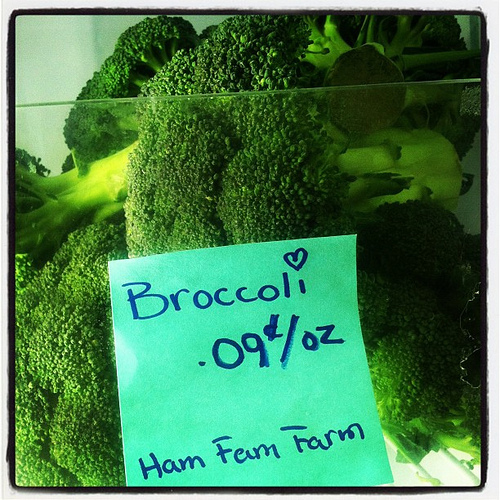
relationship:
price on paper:
[197, 310, 289, 381] [106, 228, 386, 496]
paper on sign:
[106, 228, 386, 496] [257, 309, 285, 344]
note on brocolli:
[106, 231, 396, 488] [17, 17, 479, 487]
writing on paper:
[260, 310, 279, 345] [106, 228, 386, 496]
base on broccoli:
[322, 51, 414, 135] [48, 16, 484, 230]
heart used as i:
[281, 245, 309, 270] [292, 244, 308, 298]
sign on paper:
[257, 300, 291, 360] [133, 378, 207, 433]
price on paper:
[197, 310, 346, 370] [106, 228, 386, 496]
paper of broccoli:
[106, 228, 386, 496] [18, 17, 489, 487]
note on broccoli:
[106, 231, 392, 489] [3, 48, 446, 485]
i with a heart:
[297, 278, 307, 293] [282, 247, 307, 271]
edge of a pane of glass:
[32, 104, 122, 133] [185, 77, 305, 110]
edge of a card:
[24, 398, 124, 499] [88, 230, 395, 489]